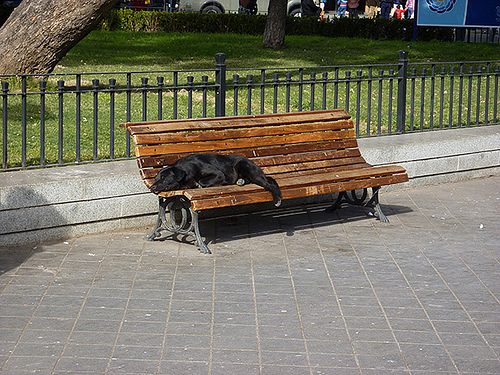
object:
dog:
[150, 152, 283, 209]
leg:
[324, 191, 345, 214]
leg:
[191, 210, 213, 254]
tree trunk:
[0, 0, 118, 75]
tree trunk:
[263, 0, 285, 47]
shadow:
[0, 184, 76, 277]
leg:
[371, 186, 391, 224]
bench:
[116, 107, 411, 255]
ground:
[0, 173, 499, 374]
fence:
[0, 51, 499, 172]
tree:
[0, 0, 109, 79]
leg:
[142, 196, 164, 242]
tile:
[213, 312, 258, 325]